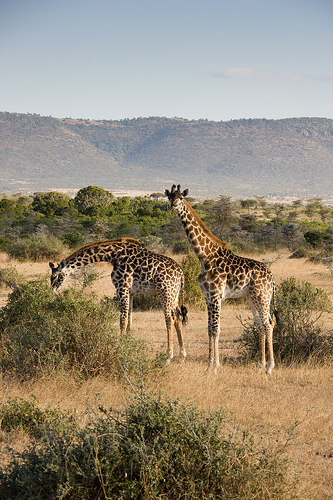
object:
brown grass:
[270, 374, 330, 420]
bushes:
[0, 392, 275, 498]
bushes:
[8, 223, 66, 261]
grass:
[1, 182, 332, 498]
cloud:
[209, 59, 261, 77]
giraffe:
[49, 236, 194, 367]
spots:
[220, 262, 225, 269]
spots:
[189, 224, 194, 232]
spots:
[253, 273, 258, 279]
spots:
[157, 264, 165, 273]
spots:
[129, 262, 136, 269]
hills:
[123, 114, 333, 191]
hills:
[0, 109, 120, 195]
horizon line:
[0, 185, 332, 200]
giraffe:
[163, 184, 280, 374]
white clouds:
[284, 82, 305, 101]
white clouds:
[223, 92, 246, 110]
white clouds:
[54, 89, 86, 105]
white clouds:
[10, 79, 36, 101]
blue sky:
[0, 0, 333, 122]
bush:
[0, 272, 170, 391]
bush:
[232, 274, 333, 366]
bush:
[113, 238, 248, 311]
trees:
[74, 182, 117, 222]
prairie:
[0, 189, 333, 499]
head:
[164, 182, 189, 208]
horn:
[171, 184, 176, 193]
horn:
[176, 184, 181, 192]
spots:
[238, 272, 245, 281]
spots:
[133, 265, 142, 275]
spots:
[86, 248, 93, 256]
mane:
[182, 198, 229, 249]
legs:
[201, 267, 227, 377]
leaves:
[18, 295, 31, 315]